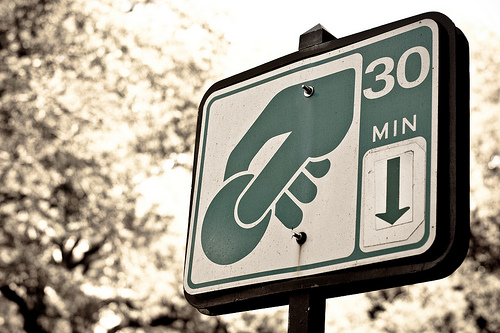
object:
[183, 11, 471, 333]
sign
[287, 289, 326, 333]
pole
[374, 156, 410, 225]
arrow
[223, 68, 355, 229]
hand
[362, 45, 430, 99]
number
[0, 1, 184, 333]
tree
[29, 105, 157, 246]
flower